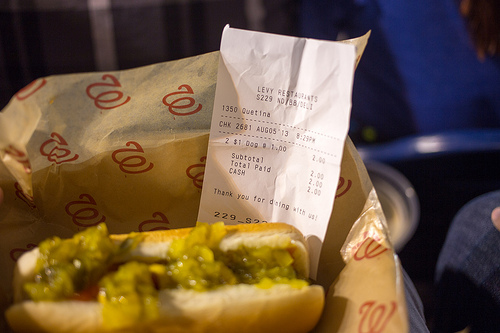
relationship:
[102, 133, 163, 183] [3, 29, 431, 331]
letter on package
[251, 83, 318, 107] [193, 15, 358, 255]
writing on receip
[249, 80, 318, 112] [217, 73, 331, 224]
writing on english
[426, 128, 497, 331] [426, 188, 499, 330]
man has blue jeans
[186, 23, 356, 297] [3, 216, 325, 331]
receipt next food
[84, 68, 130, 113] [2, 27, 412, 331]
w on paper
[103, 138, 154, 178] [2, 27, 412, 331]
w on paper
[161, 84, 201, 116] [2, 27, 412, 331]
w on paper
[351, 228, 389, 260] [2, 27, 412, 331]
w on paper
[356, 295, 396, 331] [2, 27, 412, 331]
w on paper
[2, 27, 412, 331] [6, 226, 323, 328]
paper under hotdog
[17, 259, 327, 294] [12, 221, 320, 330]
hotdog on bun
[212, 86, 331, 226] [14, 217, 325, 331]
paper under hotdog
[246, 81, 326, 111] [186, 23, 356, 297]
name on receipt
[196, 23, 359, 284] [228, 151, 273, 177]
receipt has order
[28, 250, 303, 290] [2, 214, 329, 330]
hot dog on bun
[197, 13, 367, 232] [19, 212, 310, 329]
recipe near hotdog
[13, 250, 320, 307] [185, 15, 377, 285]
hot dog near receipt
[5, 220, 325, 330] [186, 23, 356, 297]
hot dog cost in receipt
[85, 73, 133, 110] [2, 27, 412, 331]
w on paper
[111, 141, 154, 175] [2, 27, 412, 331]
w on paper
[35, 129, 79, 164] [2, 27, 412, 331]
w on paper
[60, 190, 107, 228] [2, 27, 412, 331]
w on paper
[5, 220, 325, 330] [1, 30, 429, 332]
hot dog sitting brown paper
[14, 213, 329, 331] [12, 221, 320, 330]
hot dog on a bun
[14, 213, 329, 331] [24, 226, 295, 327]
hot dog with relish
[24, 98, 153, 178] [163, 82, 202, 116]
liner with logo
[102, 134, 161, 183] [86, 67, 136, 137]
logo for restaurant chain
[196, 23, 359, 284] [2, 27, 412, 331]
receipt leaning on paper